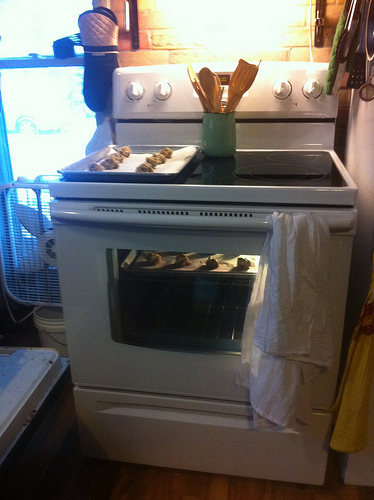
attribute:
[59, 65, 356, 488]
stove — white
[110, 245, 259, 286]
light — stove light, on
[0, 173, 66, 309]
box fan — standing, white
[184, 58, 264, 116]
utensils — wooden, wood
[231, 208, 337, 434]
towel — white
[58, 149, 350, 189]
surface — black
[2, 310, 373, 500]
floor — wood, dark, wooden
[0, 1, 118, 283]
window — tall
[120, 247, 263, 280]
tray — gray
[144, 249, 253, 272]
dough — raw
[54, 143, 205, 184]
top tray — gray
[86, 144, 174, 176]
top dough — raw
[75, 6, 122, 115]
mitt — black, white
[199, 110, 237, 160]
holder — green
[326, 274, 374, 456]
handtowel — yellow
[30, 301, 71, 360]
pail — white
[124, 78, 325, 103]
knobs — white